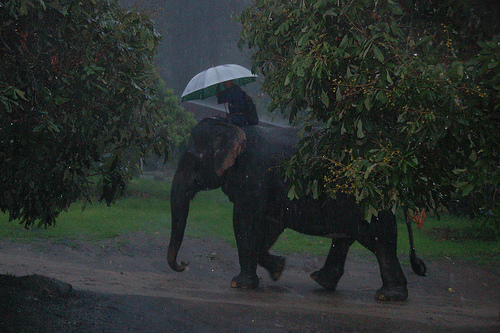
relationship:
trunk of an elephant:
[165, 157, 198, 275] [161, 113, 431, 305]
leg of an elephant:
[261, 219, 293, 278] [161, 113, 431, 305]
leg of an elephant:
[363, 228, 416, 305] [161, 113, 431, 305]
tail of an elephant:
[381, 203, 441, 299] [143, 122, 435, 317]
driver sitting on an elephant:
[216, 80, 260, 126] [108, 92, 409, 293]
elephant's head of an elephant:
[165, 116, 250, 271] [161, 113, 431, 305]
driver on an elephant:
[216, 80, 260, 126] [161, 113, 431, 305]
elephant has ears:
[161, 113, 431, 305] [207, 122, 247, 178]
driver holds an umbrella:
[216, 80, 260, 126] [182, 61, 255, 99]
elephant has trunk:
[161, 113, 431, 305] [167, 187, 192, 274]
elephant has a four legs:
[161, 113, 431, 305] [225, 195, 411, 305]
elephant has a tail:
[165, 113, 432, 301] [394, 194, 446, 288]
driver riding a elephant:
[216, 80, 260, 126] [161, 113, 431, 305]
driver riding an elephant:
[216, 80, 260, 126] [161, 113, 431, 305]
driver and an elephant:
[216, 80, 260, 126] [161, 113, 431, 305]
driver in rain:
[216, 80, 260, 126] [6, 1, 488, 316]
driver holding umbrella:
[216, 80, 260, 126] [180, 60, 254, 92]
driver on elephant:
[216, 80, 260, 126] [161, 113, 431, 305]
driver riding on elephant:
[216, 80, 260, 126] [161, 113, 431, 305]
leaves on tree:
[236, 5, 499, 285] [239, 0, 499, 240]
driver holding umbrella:
[216, 80, 260, 126] [179, 60, 260, 100]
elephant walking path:
[161, 113, 431, 305] [3, 236, 498, 331]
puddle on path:
[0, 252, 207, 299] [5, 230, 498, 327]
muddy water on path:
[23, 280, 498, 307] [41, 247, 485, 327]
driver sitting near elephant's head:
[216, 80, 260, 126] [188, 127, 314, 244]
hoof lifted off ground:
[264, 252, 289, 277] [15, 254, 498, 329]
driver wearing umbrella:
[219, 82, 259, 124] [178, 64, 253, 99]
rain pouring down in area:
[114, 16, 400, 180] [4, 9, 495, 326]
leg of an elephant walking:
[228, 203, 260, 290] [197, 200, 294, 321]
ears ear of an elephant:
[207, 122, 247, 178] [263, 138, 418, 248]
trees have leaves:
[85, 53, 142, 230] [302, 100, 447, 240]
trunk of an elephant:
[165, 157, 198, 275] [165, 149, 192, 276]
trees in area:
[0, 0, 197, 233] [3, 141, 493, 333]